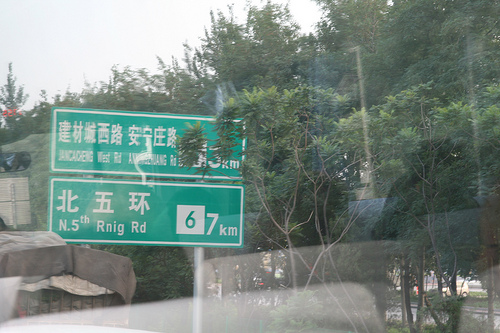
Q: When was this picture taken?
A: Daytime.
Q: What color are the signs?
A: Green.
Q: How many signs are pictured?
A: Two.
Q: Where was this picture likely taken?
A: China.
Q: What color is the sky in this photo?
A: White.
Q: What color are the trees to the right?
A: Green.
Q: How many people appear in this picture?
A: Zero.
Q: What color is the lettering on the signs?
A: White.